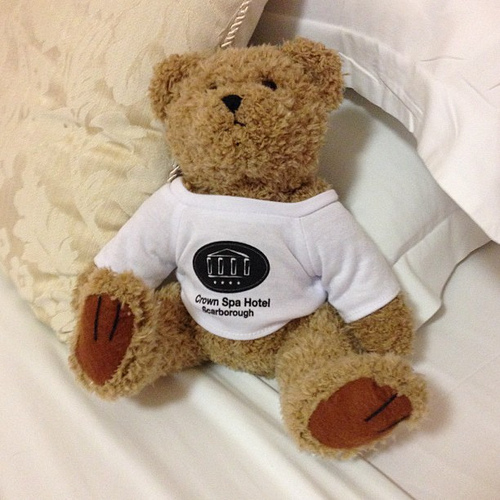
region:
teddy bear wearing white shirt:
[76, 43, 426, 460]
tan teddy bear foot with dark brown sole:
[285, 353, 442, 455]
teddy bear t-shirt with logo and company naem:
[99, 173, 397, 345]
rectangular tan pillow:
[2, 0, 274, 335]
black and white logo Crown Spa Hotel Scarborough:
[193, 238, 273, 321]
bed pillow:
[321, 97, 497, 328]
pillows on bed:
[2, 0, 497, 331]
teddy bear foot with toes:
[68, 267, 157, 397]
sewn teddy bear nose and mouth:
[219, 94, 247, 127]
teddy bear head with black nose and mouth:
[150, 42, 346, 187]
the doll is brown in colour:
[73, 45, 443, 447]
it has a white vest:
[106, 175, 413, 351]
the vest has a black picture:
[143, 172, 399, 335]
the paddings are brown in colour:
[314, 362, 417, 469]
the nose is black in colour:
[216, 89, 247, 118]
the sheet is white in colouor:
[86, 440, 256, 496]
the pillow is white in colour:
[18, 20, 130, 185]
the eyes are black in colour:
[254, 67, 286, 92]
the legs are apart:
[31, 230, 421, 453]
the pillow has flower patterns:
[26, 55, 139, 204]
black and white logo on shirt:
[185, 240, 275, 295]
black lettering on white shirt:
[194, 293, 270, 323]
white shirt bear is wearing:
[103, 180, 383, 327]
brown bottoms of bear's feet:
[74, 296, 405, 456]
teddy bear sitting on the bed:
[84, 48, 425, 448]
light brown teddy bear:
[77, 43, 426, 440]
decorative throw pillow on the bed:
[2, 1, 278, 331]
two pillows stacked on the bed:
[257, 7, 494, 319]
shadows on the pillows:
[262, 6, 477, 221]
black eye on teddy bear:
[205, 80, 215, 90]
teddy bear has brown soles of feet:
[71, 293, 141, 390]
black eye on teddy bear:
[255, 70, 275, 90]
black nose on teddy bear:
[215, 90, 240, 110]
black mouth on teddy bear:
[215, 115, 245, 130]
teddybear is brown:
[75, 35, 420, 455]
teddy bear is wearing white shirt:
[75, 35, 420, 460]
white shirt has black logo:
[95, 175, 400, 345]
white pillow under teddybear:
[323, 42, 494, 332]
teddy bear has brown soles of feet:
[311, 377, 411, 447]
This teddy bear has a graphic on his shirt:
[192, 234, 259, 314]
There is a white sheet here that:
[455, 355, 474, 438]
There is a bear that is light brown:
[324, 358, 376, 410]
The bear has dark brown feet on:
[353, 401, 368, 456]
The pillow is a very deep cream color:
[40, 52, 83, 161]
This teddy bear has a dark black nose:
[221, 87, 263, 152]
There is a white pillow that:
[426, 63, 461, 132]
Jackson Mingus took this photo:
[74, 42, 412, 466]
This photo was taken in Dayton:
[82, 41, 427, 431]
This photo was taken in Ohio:
[120, 79, 378, 438]